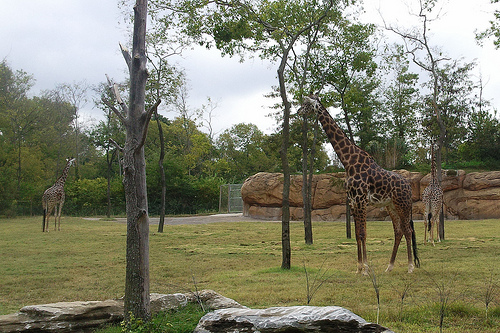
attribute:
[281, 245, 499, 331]
shrubs — spindly, little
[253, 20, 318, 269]
trunk — thin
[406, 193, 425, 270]
tail — very long, black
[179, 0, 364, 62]
leaves — green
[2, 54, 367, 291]
forest — green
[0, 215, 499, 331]
grass — dry, green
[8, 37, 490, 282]
many trees — small, delicate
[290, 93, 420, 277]
giraffe — tall, standing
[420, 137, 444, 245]
giraffe — tall, standing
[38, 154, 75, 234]
giraffe — tall, standing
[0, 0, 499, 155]
sky — cloudy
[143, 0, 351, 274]
tree — tall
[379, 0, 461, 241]
tree — tall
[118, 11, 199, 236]
tree — tall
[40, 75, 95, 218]
tree — tall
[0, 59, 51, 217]
tree — tall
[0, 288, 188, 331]
rock — flat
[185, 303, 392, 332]
rock — flat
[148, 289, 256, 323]
rock — flat